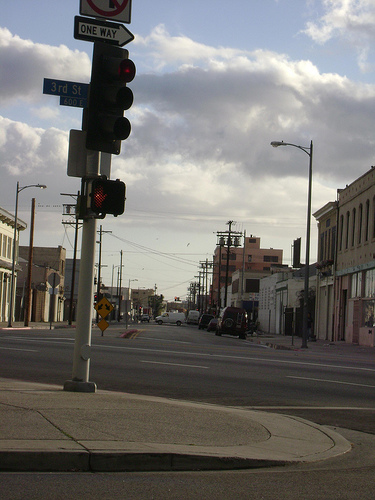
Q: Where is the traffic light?
A: On the street corner.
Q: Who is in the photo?
A: Nobody.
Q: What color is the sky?
A: Blue with white clouds.